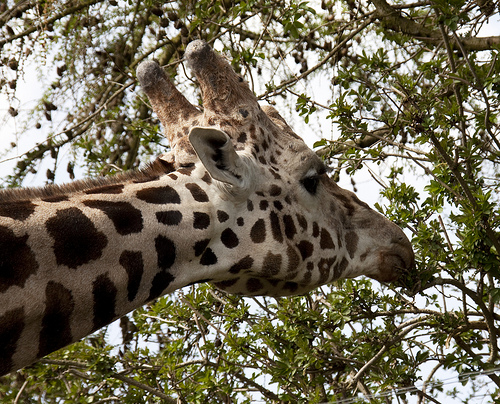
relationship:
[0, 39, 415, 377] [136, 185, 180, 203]
giraffe has spot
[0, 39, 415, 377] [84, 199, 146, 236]
giraffe has spot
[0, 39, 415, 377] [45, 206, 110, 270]
giraffe has spot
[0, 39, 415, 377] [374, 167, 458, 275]
giraffe eating foilage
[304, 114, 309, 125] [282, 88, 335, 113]
leaf attached to branch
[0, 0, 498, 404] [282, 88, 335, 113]
tree has branch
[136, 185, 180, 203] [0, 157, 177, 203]
spot near mane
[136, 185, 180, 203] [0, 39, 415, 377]
spot on giraffe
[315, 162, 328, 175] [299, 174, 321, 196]
marking above eye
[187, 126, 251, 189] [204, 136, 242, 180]
ear has inside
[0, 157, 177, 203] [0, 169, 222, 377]
mane on neck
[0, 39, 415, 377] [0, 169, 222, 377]
giraffe has neck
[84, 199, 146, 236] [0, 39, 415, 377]
spot on giraffe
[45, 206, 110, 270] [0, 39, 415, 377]
spot on giraffe